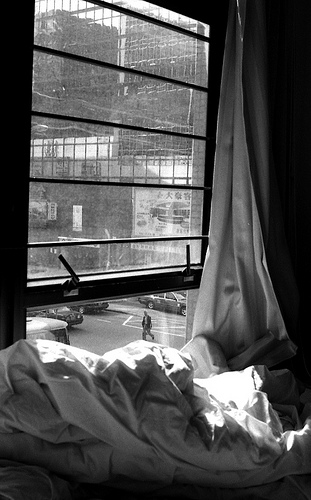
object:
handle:
[54, 247, 81, 292]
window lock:
[54, 253, 85, 298]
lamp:
[91, 346, 230, 446]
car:
[26, 303, 82, 330]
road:
[26, 306, 189, 356]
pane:
[29, 10, 206, 287]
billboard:
[132, 191, 190, 242]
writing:
[155, 192, 164, 199]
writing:
[166, 192, 172, 200]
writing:
[174, 192, 182, 200]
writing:
[184, 192, 191, 199]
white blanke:
[1, 333, 305, 484]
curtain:
[192, 0, 302, 368]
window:
[19, 0, 211, 342]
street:
[22, 258, 189, 367]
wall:
[34, 0, 211, 267]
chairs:
[139, 252, 156, 264]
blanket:
[1, 335, 310, 500]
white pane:
[31, 0, 206, 158]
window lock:
[178, 242, 197, 278]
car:
[136, 291, 187, 317]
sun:
[156, 296, 182, 348]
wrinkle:
[38, 354, 93, 393]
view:
[24, 227, 195, 331]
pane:
[174, 156, 185, 179]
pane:
[28, 38, 60, 59]